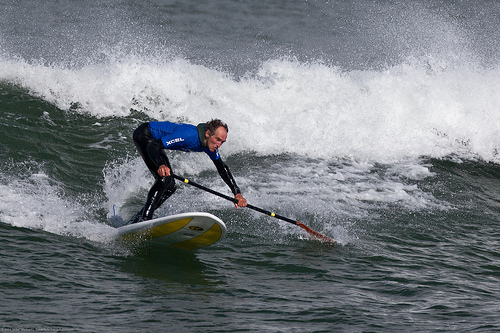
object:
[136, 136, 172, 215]
black pants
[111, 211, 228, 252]
surfboard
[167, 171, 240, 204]
long handle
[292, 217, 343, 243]
end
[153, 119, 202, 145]
blue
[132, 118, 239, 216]
wetsuit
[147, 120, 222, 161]
shirt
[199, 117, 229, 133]
hair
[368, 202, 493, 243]
water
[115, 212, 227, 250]
board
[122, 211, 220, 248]
stripe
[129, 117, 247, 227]
man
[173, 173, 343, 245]
paddle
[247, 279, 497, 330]
water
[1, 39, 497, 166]
wave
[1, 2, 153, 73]
water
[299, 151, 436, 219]
water